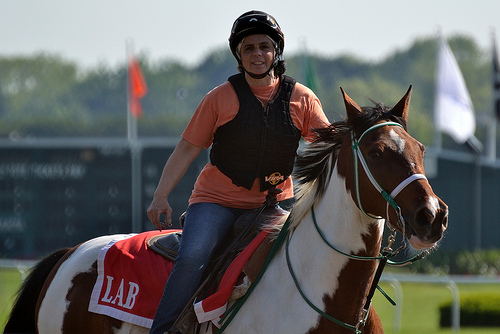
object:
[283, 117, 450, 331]
gear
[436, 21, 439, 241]
pole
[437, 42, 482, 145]
flag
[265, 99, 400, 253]
mane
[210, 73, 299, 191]
black vest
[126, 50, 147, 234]
pole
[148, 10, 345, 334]
woman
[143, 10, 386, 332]
bridal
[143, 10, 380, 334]
man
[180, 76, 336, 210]
shirt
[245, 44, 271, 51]
glasses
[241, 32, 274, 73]
face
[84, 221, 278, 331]
blanket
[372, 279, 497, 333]
ground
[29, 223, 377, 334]
horse body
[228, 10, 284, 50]
helmet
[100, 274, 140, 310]
word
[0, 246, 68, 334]
black tail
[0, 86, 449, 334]
horse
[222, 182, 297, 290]
saddle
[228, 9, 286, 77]
head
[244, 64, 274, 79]
chin strap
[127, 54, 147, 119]
flag